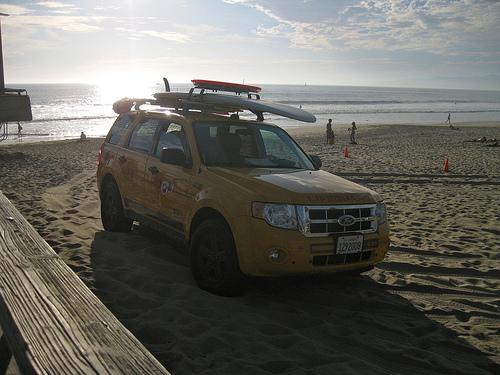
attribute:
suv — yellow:
[92, 103, 394, 294]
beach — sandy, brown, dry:
[1, 121, 499, 372]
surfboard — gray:
[154, 86, 319, 125]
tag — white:
[334, 232, 366, 254]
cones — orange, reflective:
[342, 145, 454, 171]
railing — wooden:
[3, 189, 170, 373]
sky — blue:
[8, 3, 499, 89]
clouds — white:
[7, 3, 496, 89]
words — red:
[308, 193, 372, 203]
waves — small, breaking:
[31, 103, 499, 123]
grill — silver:
[310, 206, 377, 229]